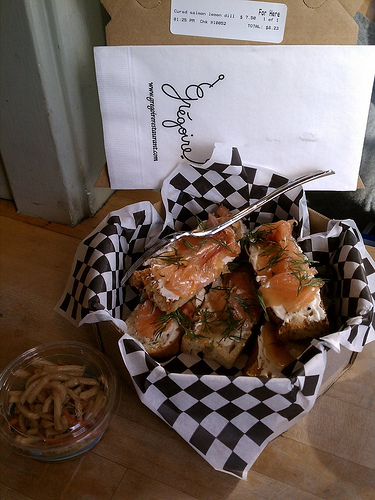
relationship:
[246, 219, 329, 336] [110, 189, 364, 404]
sandwich in basket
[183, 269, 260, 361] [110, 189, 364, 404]
sandwich in basket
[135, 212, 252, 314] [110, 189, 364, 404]
sandwich in basket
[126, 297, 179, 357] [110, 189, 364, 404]
sandwich in basket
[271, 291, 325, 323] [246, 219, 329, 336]
cream cheese on sandwich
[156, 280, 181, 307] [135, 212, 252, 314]
cream cheese on sandwich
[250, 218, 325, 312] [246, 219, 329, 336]
fish on sandwich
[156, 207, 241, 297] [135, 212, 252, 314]
fish on sandwich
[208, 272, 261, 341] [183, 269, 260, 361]
fish on sandwich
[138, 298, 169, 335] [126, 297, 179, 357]
fish on sandwich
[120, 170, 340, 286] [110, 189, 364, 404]
spoon in basket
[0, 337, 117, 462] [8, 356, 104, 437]
cup of salad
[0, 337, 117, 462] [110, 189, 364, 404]
cup next to basket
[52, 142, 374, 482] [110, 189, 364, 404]
napkin in basket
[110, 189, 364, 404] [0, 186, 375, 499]
basket on floor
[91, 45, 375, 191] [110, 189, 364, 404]
paper behind basket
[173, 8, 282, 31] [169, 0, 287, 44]
letters on label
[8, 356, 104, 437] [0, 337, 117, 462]
salad inside cup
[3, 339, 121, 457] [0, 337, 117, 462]
lid on cup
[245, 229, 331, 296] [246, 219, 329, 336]
dill on sandwich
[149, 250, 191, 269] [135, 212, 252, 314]
dill on sandwich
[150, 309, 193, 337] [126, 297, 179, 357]
dill on sandwich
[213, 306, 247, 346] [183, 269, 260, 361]
dill on sandwich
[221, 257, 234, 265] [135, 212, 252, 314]
cream cheese on sandwich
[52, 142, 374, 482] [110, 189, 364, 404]
napkin lining basket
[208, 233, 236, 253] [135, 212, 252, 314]
dill on sandwich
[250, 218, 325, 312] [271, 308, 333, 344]
fish on toast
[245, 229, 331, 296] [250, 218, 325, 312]
dill on fish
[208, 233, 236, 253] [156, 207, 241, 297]
dill on fish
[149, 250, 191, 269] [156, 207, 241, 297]
dill on fish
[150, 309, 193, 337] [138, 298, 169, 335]
dill on fish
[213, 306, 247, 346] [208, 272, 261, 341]
dill on fish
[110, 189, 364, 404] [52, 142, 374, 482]
basket with napkin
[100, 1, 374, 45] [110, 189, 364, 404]
box behind basket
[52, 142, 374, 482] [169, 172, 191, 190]
napkin has checks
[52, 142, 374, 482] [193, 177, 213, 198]
napkin has checks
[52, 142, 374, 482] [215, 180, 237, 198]
napkin has checks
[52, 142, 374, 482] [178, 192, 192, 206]
napkin has checks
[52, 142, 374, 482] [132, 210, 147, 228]
napkin has checks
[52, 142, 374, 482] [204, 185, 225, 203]
napkin has checks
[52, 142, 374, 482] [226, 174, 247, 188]
napkin has checks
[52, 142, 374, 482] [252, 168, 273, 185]
napkin has checks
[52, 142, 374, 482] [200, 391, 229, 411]
napkin has checks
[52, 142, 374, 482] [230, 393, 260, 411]
napkin has checks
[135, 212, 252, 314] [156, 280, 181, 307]
sandwich with cream cheese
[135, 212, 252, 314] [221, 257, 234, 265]
sandwich with cream cheese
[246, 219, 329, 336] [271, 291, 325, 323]
sandwich with cream cheese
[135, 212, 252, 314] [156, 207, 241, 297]
sandwich with fish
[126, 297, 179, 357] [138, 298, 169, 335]
sandwich with fish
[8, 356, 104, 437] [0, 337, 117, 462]
salad in cup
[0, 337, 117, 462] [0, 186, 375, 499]
cup on floor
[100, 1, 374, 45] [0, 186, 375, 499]
box on floor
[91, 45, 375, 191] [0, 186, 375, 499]
paper on floor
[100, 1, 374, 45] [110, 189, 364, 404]
box beside basket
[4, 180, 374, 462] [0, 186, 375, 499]
meal on floor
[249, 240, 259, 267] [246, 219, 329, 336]
cream cheese on sandwich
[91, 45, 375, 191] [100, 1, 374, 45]
paper leaning on box